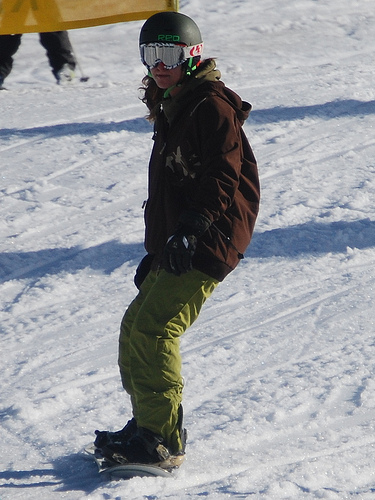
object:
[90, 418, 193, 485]
mesh sled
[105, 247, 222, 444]
snow pants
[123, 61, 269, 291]
jacket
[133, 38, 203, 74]
goggles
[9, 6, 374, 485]
snow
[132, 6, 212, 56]
helmet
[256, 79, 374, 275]
shadows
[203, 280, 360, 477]
tracks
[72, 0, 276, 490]
female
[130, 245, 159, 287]
gloves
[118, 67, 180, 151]
long hair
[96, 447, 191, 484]
snow board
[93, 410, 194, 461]
bindings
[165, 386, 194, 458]
side zipper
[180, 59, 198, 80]
green strap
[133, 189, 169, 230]
camo pocket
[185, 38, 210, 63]
red straps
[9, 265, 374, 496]
hill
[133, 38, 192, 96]
face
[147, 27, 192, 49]
green letters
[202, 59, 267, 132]
jacket hood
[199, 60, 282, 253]
back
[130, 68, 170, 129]
hair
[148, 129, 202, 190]
jacket front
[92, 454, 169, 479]
rounded edge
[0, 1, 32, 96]
legs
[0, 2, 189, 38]
banner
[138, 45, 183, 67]
eyes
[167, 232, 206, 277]
glove